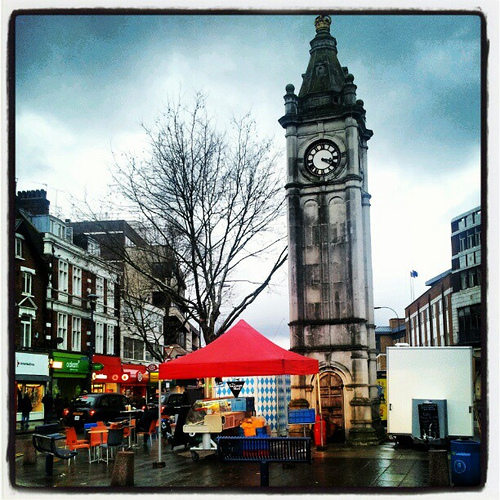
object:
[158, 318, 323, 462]
tent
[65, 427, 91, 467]
seats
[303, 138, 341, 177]
clock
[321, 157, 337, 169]
3:30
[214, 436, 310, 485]
bench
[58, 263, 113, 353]
windows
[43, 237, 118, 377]
building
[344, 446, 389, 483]
pavement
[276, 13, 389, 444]
tower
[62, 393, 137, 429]
car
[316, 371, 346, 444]
door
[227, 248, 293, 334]
branch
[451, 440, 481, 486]
bin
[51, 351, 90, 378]
sign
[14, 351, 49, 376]
sign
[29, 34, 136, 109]
sky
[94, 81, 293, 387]
tree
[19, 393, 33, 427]
people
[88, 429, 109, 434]
table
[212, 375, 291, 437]
wall